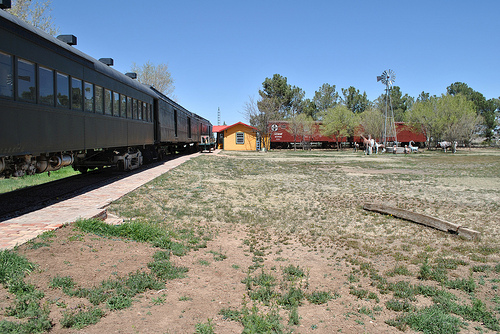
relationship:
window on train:
[7, 48, 69, 163] [8, 22, 157, 152]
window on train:
[15, 58, 40, 104] [1, 0, 210, 205]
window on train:
[36, 65, 55, 104] [1, 0, 210, 205]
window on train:
[56, 70, 70, 105] [1, 0, 210, 205]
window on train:
[70, 75, 84, 110] [1, 0, 210, 205]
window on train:
[81, 81, 95, 113] [1, 0, 210, 205]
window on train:
[15, 58, 40, 104] [0, 6, 217, 184]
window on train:
[36, 65, 55, 104] [0, 6, 217, 184]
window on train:
[70, 75, 84, 110] [0, 6, 217, 184]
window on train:
[56, 70, 70, 105] [0, 6, 217, 184]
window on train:
[96, 84, 103, 114] [0, 6, 217, 184]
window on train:
[111, 92, 120, 118] [0, 6, 217, 184]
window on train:
[93, 83, 111, 112] [0, 6, 217, 184]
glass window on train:
[108, 90, 132, 115] [4, 12, 238, 168]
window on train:
[125, 97, 138, 120] [0, 6, 217, 184]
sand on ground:
[1, 139, 498, 332] [0, 148, 496, 329]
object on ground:
[360, 197, 485, 243] [0, 148, 496, 329]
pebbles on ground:
[340, 294, 391, 332] [186, 279, 251, 314]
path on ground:
[0, 151, 202, 257] [19, 147, 369, 330]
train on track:
[0, 6, 217, 184] [0, 143, 187, 258]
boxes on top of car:
[46, 21, 127, 96] [2, 1, 157, 175]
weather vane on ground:
[374, 67, 400, 154] [0, 148, 496, 329]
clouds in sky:
[88, 7, 265, 96] [5, 0, 498, 122]